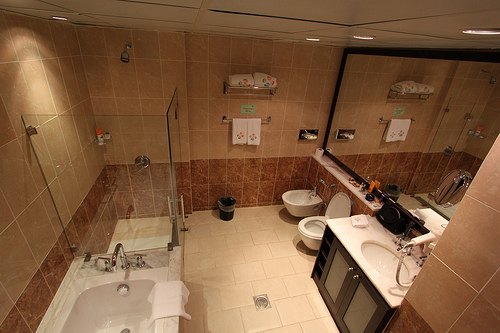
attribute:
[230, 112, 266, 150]
towels — white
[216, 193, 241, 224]
can — black, garbage can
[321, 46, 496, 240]
mirror — long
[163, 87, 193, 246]
doors — glass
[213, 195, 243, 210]
bag — plastic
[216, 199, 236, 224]
can — black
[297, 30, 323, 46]
lights — recessed 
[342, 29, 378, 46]
lights — recessed 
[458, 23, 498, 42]
lights — recessed 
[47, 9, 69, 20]
lights — recessed 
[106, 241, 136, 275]
faucet — curved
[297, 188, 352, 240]
seat — up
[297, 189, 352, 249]
toilet — open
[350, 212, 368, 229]
wash cloth — small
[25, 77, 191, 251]
wall — glass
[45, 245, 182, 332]
tub — white, marble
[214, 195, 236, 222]
trash can — black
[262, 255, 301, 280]
tile — white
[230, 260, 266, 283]
tile — white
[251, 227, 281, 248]
tile — white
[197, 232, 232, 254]
tile — white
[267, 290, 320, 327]
tile — white